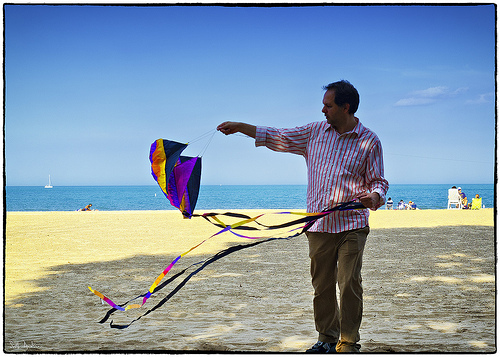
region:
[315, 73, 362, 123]
the head of a man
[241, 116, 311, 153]
the arm of a man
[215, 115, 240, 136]
the hand of a man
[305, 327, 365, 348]
a pair of shoes on the man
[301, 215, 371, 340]
a pair of brown pants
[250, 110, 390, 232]
a white and orange striped shirt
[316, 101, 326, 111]
the nose of a man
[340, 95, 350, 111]
the ear of a man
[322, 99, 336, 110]
the eye of a man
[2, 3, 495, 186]
a clear blue sky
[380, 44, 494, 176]
The sky is clear.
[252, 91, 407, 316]
The man is wearing a stripped shirt.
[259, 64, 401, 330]
The man is wearing tan pants.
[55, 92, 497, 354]
The man is standing in a shadow.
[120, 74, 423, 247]
The man is holding a kite.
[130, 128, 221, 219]
The kite is colorful.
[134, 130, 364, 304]
The kite has a long tail.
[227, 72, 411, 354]
The man is on the beach.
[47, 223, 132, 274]
The ground is sandy.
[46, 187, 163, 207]
The water is clear.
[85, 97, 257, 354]
colorful kite with tail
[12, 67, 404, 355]
man flying a kite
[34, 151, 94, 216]
boat on a water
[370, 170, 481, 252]
people sitting on beach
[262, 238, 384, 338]
a pair of tan pants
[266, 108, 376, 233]
a red and white shirt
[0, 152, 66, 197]
white sail boat on water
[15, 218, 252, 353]
shadow on the sand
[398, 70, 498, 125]
blue sky with white cloud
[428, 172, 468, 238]
person on white chair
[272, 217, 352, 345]
A man wearing khaki pants.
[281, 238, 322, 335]
A man wearing khaki pants.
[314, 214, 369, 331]
A man wearing khaki pants.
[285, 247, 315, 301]
A man wearing khaki pants.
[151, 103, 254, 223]
man holding a kite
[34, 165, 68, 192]
boat in the water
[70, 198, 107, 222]
person laying on the beach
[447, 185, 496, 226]
people sitting on the beach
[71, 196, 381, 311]
the kite's tail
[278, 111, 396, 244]
man's shirt is red and white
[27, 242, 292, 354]
shadows on the sand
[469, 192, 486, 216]
the chair is yellow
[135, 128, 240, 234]
the kite is multi colored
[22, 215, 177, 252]
the sand is tan